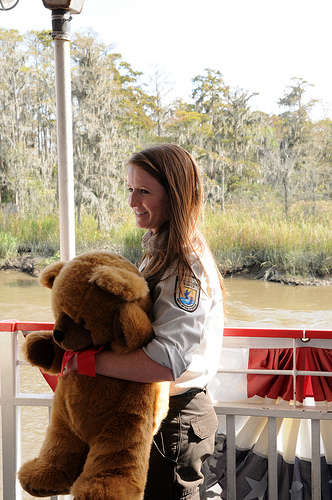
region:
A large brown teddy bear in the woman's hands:
[24, 253, 168, 492]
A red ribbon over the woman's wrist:
[56, 345, 109, 380]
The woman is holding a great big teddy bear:
[26, 252, 190, 470]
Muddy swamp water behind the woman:
[239, 282, 316, 324]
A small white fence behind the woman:
[228, 401, 329, 498]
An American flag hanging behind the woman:
[212, 338, 322, 498]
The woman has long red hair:
[119, 146, 218, 288]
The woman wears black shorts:
[143, 388, 228, 497]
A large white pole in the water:
[46, 36, 90, 263]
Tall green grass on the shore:
[206, 217, 317, 252]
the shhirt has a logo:
[172, 265, 203, 326]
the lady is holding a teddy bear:
[0, 180, 242, 496]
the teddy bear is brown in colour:
[23, 251, 156, 481]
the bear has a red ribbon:
[46, 340, 113, 379]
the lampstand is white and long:
[54, 33, 77, 263]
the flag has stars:
[246, 334, 326, 497]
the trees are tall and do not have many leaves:
[112, 77, 236, 129]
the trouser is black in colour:
[168, 395, 208, 498]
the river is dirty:
[270, 288, 314, 312]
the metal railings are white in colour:
[236, 402, 327, 497]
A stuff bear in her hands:
[24, 256, 143, 499]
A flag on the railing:
[212, 333, 328, 499]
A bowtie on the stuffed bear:
[60, 342, 98, 369]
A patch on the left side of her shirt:
[174, 276, 201, 309]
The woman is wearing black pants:
[148, 382, 216, 499]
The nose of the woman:
[129, 191, 138, 205]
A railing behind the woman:
[0, 322, 331, 499]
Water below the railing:
[5, 284, 329, 446]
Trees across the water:
[192, 74, 311, 209]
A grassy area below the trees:
[5, 208, 324, 245]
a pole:
[49, 88, 89, 236]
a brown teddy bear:
[41, 259, 146, 477]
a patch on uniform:
[177, 275, 203, 311]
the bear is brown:
[80, 399, 141, 463]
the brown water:
[245, 289, 318, 326]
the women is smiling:
[129, 206, 148, 217]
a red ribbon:
[73, 355, 102, 384]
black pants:
[166, 412, 219, 496]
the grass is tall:
[234, 199, 276, 261]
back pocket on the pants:
[187, 417, 223, 437]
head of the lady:
[101, 144, 202, 239]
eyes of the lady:
[123, 182, 158, 199]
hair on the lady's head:
[164, 151, 207, 261]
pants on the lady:
[164, 399, 219, 491]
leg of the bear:
[85, 433, 148, 495]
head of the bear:
[53, 252, 127, 345]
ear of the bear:
[104, 260, 138, 295]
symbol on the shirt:
[167, 266, 208, 321]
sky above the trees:
[191, 33, 239, 63]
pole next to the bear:
[34, 114, 99, 203]